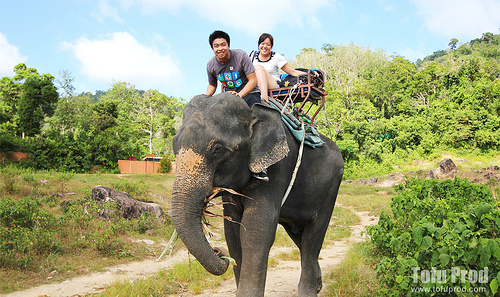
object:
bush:
[358, 176, 500, 296]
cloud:
[67, 27, 184, 89]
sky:
[15, 4, 144, 37]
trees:
[357, 30, 499, 154]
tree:
[0, 61, 60, 137]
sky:
[307, 0, 500, 58]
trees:
[291, 41, 387, 163]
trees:
[96, 79, 191, 157]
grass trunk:
[170, 149, 230, 276]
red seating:
[267, 67, 328, 127]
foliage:
[426, 184, 487, 204]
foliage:
[455, 65, 496, 88]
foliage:
[7, 73, 37, 99]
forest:
[471, 31, 499, 44]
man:
[199, 29, 262, 105]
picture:
[0, 0, 499, 296]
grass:
[0, 215, 146, 281]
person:
[246, 32, 321, 104]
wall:
[120, 161, 158, 174]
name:
[409, 265, 489, 284]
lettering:
[403, 284, 489, 294]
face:
[257, 37, 273, 55]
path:
[0, 197, 378, 296]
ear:
[248, 101, 291, 173]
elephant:
[170, 92, 344, 296]